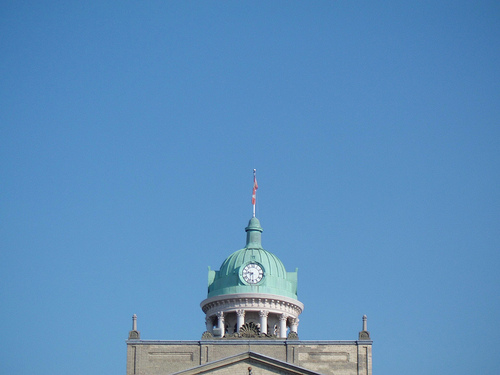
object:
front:
[123, 168, 373, 375]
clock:
[242, 263, 264, 284]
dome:
[218, 248, 287, 280]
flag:
[251, 175, 258, 205]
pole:
[252, 172, 255, 218]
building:
[123, 168, 376, 375]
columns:
[206, 309, 299, 339]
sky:
[0, 0, 500, 375]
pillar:
[236, 309, 246, 334]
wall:
[130, 344, 361, 375]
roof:
[245, 217, 264, 250]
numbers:
[252, 279, 255, 283]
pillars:
[258, 310, 269, 337]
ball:
[253, 168, 257, 173]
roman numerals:
[243, 276, 248, 280]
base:
[199, 292, 304, 340]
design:
[239, 321, 260, 338]